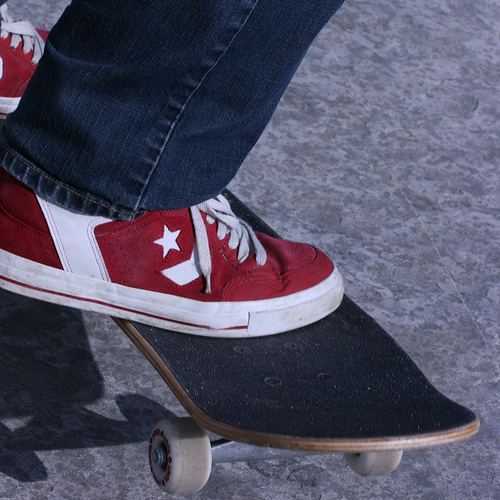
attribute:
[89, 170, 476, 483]
skatebord — black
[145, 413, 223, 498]
wheel — white, plastic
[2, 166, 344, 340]
tennis shoe — red, rubber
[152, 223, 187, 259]
star design — white, classic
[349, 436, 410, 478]
wheel — white, plastic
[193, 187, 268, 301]
laces — white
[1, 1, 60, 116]
tennis shoe — red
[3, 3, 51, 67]
laces — white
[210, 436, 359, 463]
axel — silver, metal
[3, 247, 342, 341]
rubber — white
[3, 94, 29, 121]
rubber — white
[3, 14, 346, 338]
shoes — red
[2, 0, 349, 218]
jeans — blue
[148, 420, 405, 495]
wheels — white, polyurethane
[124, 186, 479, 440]
grip tape — black, rough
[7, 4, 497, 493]
ground — concrete, smooth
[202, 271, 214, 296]
aglet — white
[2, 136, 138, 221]
stitching — orange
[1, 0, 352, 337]
person — standing, skateboarding